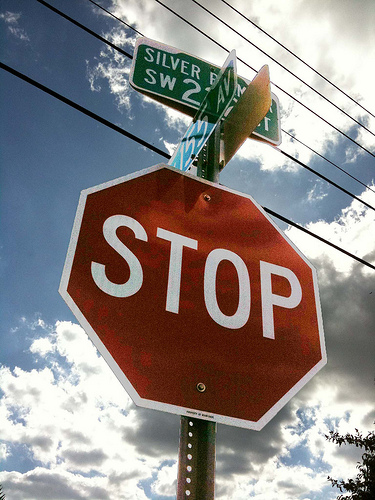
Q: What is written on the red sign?
A: Stop.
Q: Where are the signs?
A: On pole.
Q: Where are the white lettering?
A: On red background.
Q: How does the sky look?
A: Very cloudy.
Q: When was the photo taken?
A: Sunny day.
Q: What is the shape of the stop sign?
A: Octagon.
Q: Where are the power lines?
A: Above signs.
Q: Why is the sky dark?
A: Cloudy.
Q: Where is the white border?
A: On green sign.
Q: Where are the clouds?
A: In sky.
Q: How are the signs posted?
A: On a pole.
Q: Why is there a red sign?
A: Make traffic stop.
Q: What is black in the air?
A: Wires.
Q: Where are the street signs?
A: Above stop sign.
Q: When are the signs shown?
A: Cloudy day.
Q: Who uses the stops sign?
A: Driver.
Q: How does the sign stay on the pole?
A: Bolts.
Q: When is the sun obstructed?
A: Cloud day.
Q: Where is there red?
A: Stop sign.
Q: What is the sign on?
A: A pole.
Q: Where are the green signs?
A: Above the stop sign.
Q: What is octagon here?
A: The stop sign.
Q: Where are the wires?
A: Above the signs.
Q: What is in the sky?
A: Clouds.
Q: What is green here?
A: The signs.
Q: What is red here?
A: The sign.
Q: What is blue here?
A: The sky.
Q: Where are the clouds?
A: In the sky.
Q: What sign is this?
A: Stop sign.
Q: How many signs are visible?
A: Four.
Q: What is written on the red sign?
A: Stop.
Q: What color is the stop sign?
A: Red and white.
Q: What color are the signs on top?
A: Green and white.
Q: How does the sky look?
A: Cloudy.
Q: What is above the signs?
A: Wires.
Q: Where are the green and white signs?
A: At the very top of the post.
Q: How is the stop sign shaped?
A: An octagon.